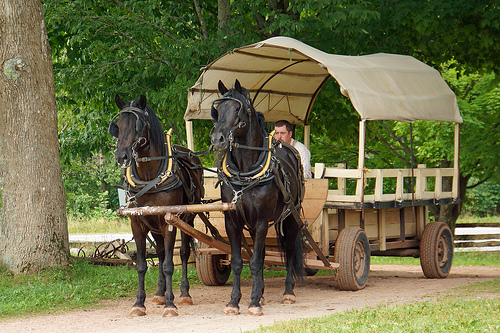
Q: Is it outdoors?
A: Yes, it is outdoors.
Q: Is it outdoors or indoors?
A: It is outdoors.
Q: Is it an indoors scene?
A: No, it is outdoors.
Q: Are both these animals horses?
A: Yes, all the animals are horses.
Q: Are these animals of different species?
A: No, all the animals are horses.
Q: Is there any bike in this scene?
A: No, there are no bikes.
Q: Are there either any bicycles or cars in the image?
A: No, there are no bicycles or cars.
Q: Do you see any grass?
A: Yes, there is grass.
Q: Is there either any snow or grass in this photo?
A: Yes, there is grass.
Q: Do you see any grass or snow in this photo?
A: Yes, there is grass.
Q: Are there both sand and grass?
A: No, there is grass but no sand.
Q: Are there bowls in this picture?
A: No, there are no bowls.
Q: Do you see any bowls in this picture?
A: No, there are no bowls.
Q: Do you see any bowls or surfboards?
A: No, there are no bowls or surfboards.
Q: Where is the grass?
A: The grass is in the field.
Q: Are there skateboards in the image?
A: No, there are no skateboards.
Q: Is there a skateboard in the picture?
A: No, there are no skateboards.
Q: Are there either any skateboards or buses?
A: No, there are no skateboards or buses.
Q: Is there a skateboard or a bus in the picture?
A: No, there are no skateboards or buses.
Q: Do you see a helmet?
A: No, there are no helmets.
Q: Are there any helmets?
A: No, there are no helmets.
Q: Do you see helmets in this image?
A: No, there are no helmets.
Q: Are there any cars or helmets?
A: No, there are no helmets or cars.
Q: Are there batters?
A: No, there are no batters.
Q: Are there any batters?
A: No, there are no batters.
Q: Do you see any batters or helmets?
A: No, there are no batters or helmets.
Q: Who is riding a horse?
A: The man is riding a horse.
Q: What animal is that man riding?
A: The man is riding a horse.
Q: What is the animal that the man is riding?
A: The animal is a horse.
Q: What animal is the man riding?
A: The man is riding a horse.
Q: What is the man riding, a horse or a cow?
A: The man is riding a horse.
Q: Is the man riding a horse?
A: Yes, the man is riding a horse.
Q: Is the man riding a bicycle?
A: No, the man is riding a horse.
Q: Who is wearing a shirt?
A: The man is wearing a shirt.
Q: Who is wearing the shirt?
A: The man is wearing a shirt.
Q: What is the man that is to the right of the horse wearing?
A: The man is wearing a shirt.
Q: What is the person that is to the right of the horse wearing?
A: The man is wearing a shirt.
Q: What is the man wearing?
A: The man is wearing a shirt.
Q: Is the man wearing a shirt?
A: Yes, the man is wearing a shirt.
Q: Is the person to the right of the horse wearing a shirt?
A: Yes, the man is wearing a shirt.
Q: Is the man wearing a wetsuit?
A: No, the man is wearing a shirt.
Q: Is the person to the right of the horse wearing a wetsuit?
A: No, the man is wearing a shirt.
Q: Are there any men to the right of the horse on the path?
A: Yes, there is a man to the right of the horse.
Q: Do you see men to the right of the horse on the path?
A: Yes, there is a man to the right of the horse.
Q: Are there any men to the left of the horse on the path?
A: No, the man is to the right of the horse.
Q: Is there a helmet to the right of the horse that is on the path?
A: No, there is a man to the right of the horse.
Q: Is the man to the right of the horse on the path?
A: Yes, the man is to the right of the horse.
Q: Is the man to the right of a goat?
A: No, the man is to the right of the horse.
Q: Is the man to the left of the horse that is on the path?
A: No, the man is to the right of the horse.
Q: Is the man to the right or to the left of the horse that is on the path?
A: The man is to the right of the horse.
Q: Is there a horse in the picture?
A: Yes, there is a horse.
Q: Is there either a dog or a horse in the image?
A: Yes, there is a horse.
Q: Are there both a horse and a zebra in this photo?
A: No, there is a horse but no zebras.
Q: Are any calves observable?
A: No, there are no calves.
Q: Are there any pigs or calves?
A: No, there are no calves or pigs.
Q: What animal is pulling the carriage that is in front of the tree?
A: The horse is pulling the carriage.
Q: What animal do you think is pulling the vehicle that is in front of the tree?
A: The horse is pulling the carriage.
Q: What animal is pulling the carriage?
A: The horse is pulling the carriage.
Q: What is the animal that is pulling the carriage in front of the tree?
A: The animal is a horse.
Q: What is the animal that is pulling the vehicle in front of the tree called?
A: The animal is a horse.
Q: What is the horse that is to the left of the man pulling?
A: The horse is pulling the carriage.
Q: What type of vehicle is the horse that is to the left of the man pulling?
A: The horse is pulling the carriage.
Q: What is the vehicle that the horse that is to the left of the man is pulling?
A: The vehicle is a carriage.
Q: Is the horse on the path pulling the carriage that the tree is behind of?
A: Yes, the horse is pulling the carriage.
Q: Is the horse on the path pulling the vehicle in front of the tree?
A: Yes, the horse is pulling the carriage.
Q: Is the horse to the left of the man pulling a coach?
A: No, the horse is pulling the carriage.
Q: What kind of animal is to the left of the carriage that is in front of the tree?
A: The animal is a horse.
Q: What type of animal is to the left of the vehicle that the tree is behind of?
A: The animal is a horse.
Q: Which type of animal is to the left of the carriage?
A: The animal is a horse.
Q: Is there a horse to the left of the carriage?
A: Yes, there is a horse to the left of the carriage.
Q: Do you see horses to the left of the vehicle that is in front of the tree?
A: Yes, there is a horse to the left of the carriage.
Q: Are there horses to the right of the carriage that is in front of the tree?
A: No, the horse is to the left of the carriage.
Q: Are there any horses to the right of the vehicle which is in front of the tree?
A: No, the horse is to the left of the carriage.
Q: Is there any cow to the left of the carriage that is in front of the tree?
A: No, there is a horse to the left of the carriage.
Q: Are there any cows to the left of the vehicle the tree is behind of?
A: No, there is a horse to the left of the carriage.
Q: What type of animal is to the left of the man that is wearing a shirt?
A: The animal is a horse.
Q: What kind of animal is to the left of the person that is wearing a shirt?
A: The animal is a horse.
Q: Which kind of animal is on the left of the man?
A: The animal is a horse.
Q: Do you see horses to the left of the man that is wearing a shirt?
A: Yes, there is a horse to the left of the man.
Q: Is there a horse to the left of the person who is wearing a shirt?
A: Yes, there is a horse to the left of the man.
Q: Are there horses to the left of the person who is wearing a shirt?
A: Yes, there is a horse to the left of the man.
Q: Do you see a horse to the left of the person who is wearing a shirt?
A: Yes, there is a horse to the left of the man.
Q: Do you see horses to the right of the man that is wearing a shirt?
A: No, the horse is to the left of the man.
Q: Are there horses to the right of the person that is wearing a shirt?
A: No, the horse is to the left of the man.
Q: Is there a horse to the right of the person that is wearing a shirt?
A: No, the horse is to the left of the man.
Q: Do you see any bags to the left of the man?
A: No, there is a horse to the left of the man.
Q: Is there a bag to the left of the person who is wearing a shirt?
A: No, there is a horse to the left of the man.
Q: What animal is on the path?
A: The animal is a horse.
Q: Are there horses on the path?
A: Yes, there is a horse on the path.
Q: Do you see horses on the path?
A: Yes, there is a horse on the path.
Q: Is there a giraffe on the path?
A: No, there is a horse on the path.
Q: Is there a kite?
A: No, there are no kites.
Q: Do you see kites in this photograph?
A: No, there are no kites.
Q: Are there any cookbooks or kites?
A: No, there are no kites or cookbooks.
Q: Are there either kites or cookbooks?
A: No, there are no kites or cookbooks.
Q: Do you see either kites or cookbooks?
A: No, there are no kites or cookbooks.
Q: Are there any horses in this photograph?
A: Yes, there is a horse.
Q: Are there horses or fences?
A: Yes, there is a horse.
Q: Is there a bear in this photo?
A: No, there are no bears.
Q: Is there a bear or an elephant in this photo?
A: No, there are no bears or elephants.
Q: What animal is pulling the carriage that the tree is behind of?
A: The horse is pulling the carriage.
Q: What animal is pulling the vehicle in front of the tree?
A: The horse is pulling the carriage.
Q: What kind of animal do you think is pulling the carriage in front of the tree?
A: The animal is a horse.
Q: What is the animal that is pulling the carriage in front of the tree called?
A: The animal is a horse.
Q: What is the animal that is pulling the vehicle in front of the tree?
A: The animal is a horse.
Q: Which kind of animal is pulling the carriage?
A: The animal is a horse.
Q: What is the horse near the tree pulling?
A: The horse is pulling the carriage.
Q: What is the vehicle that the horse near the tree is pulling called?
A: The vehicle is a carriage.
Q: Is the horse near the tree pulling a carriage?
A: Yes, the horse is pulling a carriage.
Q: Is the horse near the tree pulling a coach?
A: No, the horse is pulling a carriage.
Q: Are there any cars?
A: No, there are no cars.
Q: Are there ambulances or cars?
A: No, there are no cars or ambulances.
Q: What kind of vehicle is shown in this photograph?
A: The vehicle is a carriage.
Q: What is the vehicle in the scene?
A: The vehicle is a carriage.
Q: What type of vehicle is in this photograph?
A: The vehicle is a carriage.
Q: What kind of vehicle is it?
A: The vehicle is a carriage.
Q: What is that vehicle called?
A: This is a carriage.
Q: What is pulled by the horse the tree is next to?
A: The carriage is pulled by the horse.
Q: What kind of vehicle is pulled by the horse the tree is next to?
A: The vehicle is a carriage.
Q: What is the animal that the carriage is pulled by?
A: The animal is a horse.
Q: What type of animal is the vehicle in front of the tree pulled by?
A: The carriage is pulled by the horse.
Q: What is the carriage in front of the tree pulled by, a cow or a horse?
A: The carriage is pulled by a horse.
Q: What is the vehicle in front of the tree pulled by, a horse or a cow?
A: The carriage is pulled by a horse.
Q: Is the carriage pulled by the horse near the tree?
A: Yes, the carriage is pulled by the horse.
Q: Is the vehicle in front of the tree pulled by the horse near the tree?
A: Yes, the carriage is pulled by the horse.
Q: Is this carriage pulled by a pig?
A: No, the carriage is pulled by the horse.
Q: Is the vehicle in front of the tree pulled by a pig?
A: No, the carriage is pulled by the horse.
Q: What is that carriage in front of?
A: The carriage is in front of the tree.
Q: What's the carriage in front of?
A: The carriage is in front of the tree.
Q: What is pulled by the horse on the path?
A: The carriage is pulled by the horse.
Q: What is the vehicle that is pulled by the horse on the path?
A: The vehicle is a carriage.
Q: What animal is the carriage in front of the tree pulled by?
A: The carriage is pulled by the horse.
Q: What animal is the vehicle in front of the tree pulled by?
A: The carriage is pulled by the horse.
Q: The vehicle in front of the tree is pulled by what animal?
A: The carriage is pulled by the horse.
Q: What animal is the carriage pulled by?
A: The carriage is pulled by the horse.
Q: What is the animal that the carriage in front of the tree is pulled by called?
A: The animal is a horse.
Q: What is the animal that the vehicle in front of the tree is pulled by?
A: The animal is a horse.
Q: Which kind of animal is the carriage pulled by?
A: The carriage is pulled by the horse.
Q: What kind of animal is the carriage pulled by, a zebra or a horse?
A: The carriage is pulled by a horse.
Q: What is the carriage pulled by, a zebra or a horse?
A: The carriage is pulled by a horse.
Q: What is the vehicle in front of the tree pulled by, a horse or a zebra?
A: The carriage is pulled by a horse.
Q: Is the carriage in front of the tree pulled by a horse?
A: Yes, the carriage is pulled by a horse.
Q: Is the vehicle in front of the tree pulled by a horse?
A: Yes, the carriage is pulled by a horse.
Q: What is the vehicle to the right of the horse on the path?
A: The vehicle is a carriage.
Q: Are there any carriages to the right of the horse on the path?
A: Yes, there is a carriage to the right of the horse.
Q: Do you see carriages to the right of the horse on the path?
A: Yes, there is a carriage to the right of the horse.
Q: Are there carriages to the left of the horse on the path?
A: No, the carriage is to the right of the horse.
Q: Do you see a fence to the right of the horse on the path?
A: No, there is a carriage to the right of the horse.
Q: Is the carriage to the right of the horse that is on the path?
A: Yes, the carriage is to the right of the horse.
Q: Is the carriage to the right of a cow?
A: No, the carriage is to the right of the horse.